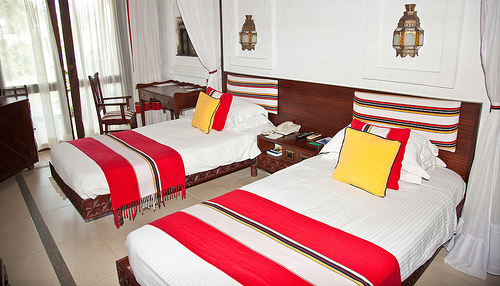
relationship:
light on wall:
[385, 5, 424, 57] [335, 20, 370, 57]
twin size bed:
[150, 124, 355, 228] [176, 113, 244, 174]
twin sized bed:
[273, 124, 355, 285] [226, 164, 399, 211]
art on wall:
[174, 16, 196, 80] [335, 20, 370, 57]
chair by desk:
[84, 80, 125, 121] [140, 78, 187, 120]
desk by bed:
[140, 78, 187, 120] [176, 113, 244, 174]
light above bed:
[236, 17, 273, 47] [176, 113, 244, 174]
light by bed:
[385, 5, 424, 57] [226, 164, 399, 211]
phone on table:
[275, 121, 304, 138] [254, 140, 292, 168]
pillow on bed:
[349, 124, 391, 193] [226, 164, 399, 211]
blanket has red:
[94, 127, 163, 208] [142, 140, 182, 187]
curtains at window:
[10, 19, 61, 121] [61, 8, 82, 107]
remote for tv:
[298, 126, 309, 142] [1, 72, 6, 104]